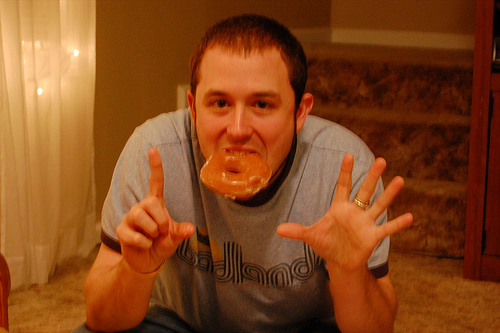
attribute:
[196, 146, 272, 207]
doughnut — brown, krispy kreme, frosting, glazed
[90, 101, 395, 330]
shirt — grey, gray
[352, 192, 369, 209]
ring — wedding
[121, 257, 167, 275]
band — rubber, yellow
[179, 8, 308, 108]
hair — short, dark, brown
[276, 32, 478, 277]
steps — brown, leading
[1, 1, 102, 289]
curtains — white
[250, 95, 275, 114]
eyes — man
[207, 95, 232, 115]
eyes — man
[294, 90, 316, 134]
ear — man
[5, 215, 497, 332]
carpet — ground, brown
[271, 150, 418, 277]
5 — man